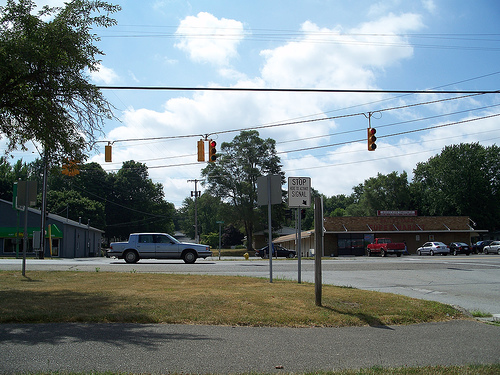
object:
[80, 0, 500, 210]
clouds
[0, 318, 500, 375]
walkway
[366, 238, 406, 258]
truck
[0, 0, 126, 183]
tree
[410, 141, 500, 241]
tree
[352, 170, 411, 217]
tree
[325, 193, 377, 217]
tree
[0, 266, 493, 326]
grass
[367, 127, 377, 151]
stoplight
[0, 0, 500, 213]
sky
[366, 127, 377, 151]
street light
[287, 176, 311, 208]
sign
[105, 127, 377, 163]
signal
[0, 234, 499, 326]
road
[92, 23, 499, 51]
power line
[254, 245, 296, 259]
cars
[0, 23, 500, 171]
lines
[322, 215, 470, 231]
roof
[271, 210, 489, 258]
building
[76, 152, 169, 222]
dough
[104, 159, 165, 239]
tree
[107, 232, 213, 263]
car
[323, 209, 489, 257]
business